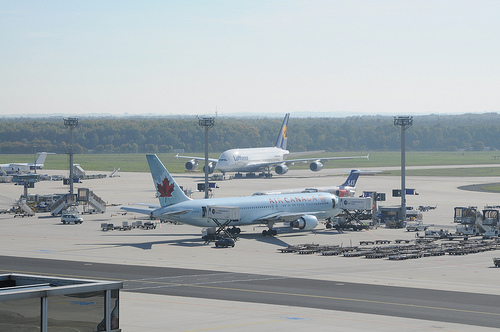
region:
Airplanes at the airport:
[144, 110, 364, 227]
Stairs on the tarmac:
[79, 185, 107, 212]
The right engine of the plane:
[295, 211, 315, 231]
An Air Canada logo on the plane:
[266, 191, 321, 203]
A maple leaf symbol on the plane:
[156, 175, 176, 199]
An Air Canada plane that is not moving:
[133, 154, 339, 238]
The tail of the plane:
[139, 154, 189, 202]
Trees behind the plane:
[94, 122, 192, 147]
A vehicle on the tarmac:
[62, 215, 84, 225]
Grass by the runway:
[428, 167, 499, 174]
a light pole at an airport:
[387, 109, 411, 230]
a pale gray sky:
[0, 2, 496, 115]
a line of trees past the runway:
[0, 114, 498, 154]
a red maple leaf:
[151, 173, 177, 201]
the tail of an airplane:
[142, 150, 186, 207]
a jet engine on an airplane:
[288, 211, 319, 233]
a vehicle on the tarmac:
[54, 210, 83, 226]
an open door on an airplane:
[329, 195, 338, 211]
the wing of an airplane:
[247, 150, 373, 173]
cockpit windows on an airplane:
[212, 153, 232, 165]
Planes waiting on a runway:
[127, 119, 374, 243]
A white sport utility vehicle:
[55, 209, 89, 229]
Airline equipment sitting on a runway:
[365, 200, 495, 272]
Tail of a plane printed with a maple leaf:
[130, 148, 202, 213]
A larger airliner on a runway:
[171, 113, 370, 180]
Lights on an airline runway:
[379, 109, 426, 239]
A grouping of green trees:
[85, 108, 147, 162]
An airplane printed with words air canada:
[134, 148, 345, 246]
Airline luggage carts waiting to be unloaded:
[92, 215, 162, 237]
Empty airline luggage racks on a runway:
[275, 239, 483, 264]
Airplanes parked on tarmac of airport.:
[121, 111, 381, 231]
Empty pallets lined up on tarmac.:
[277, 239, 481, 266]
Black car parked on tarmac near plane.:
[213, 236, 238, 251]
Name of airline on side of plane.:
[262, 193, 327, 207]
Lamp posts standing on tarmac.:
[56, 113, 226, 201]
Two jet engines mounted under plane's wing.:
[272, 161, 334, 176]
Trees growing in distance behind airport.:
[81, 110, 218, 161]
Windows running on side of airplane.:
[241, 201, 298, 216]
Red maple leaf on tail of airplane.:
[151, 171, 182, 203]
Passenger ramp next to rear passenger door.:
[199, 201, 242, 237]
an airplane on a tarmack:
[120, 150, 335, 230]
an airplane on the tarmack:
[175, 110, 365, 175]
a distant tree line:
[0, 110, 497, 160]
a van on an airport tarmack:
[56, 210, 78, 220]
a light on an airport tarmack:
[391, 111, 411, 221]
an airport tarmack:
[0, 160, 498, 328]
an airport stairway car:
[450, 205, 477, 232]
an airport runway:
[0, 250, 498, 325]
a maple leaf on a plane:
[155, 175, 174, 200]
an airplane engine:
[289, 215, 319, 228]